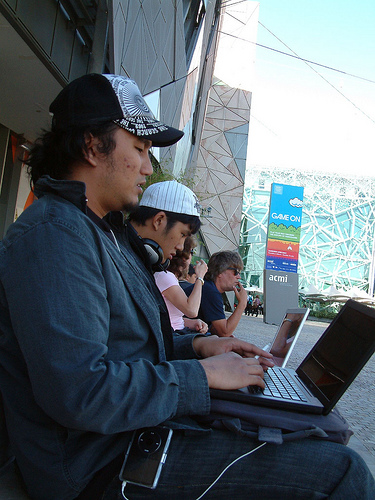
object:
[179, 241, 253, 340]
people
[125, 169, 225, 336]
man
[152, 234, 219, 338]
player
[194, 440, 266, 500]
cord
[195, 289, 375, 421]
laptop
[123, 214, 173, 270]
headphone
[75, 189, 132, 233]
neck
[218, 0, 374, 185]
sky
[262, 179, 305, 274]
sign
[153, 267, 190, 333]
shirt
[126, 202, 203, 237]
hair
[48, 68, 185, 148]
cap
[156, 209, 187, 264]
face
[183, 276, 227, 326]
jacket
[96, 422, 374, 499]
jean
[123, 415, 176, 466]
ipod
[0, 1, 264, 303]
building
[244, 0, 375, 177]
day